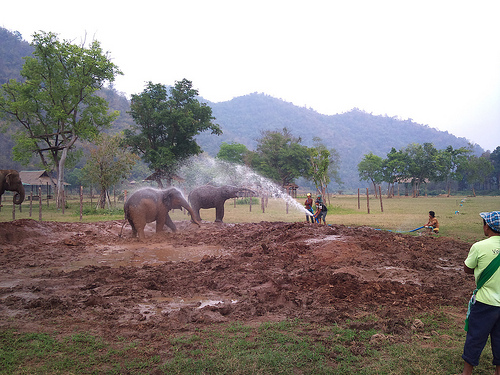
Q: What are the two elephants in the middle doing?
A: Being washed.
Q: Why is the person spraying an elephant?
A: It is getting a bath.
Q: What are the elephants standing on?
A: Mud.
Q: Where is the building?
A: In the background to the left.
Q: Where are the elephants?
A: Dirt mound.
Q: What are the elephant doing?
A: Playing in water.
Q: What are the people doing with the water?
A: Spraying the elephants.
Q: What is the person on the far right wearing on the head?
A: Hat.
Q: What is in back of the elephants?
A: Trees.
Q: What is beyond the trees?
A: Mountains.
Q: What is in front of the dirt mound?
A: Grass.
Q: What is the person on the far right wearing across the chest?
A: Green bag.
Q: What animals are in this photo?
A: Elephants.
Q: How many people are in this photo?
A: Four.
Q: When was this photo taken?
A: Daytime.